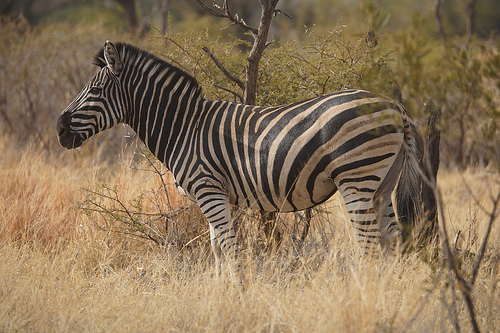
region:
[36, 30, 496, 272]
zebra is black and white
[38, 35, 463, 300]
zebra standing in tall grass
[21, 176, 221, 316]
grass ranging from light brown to blonde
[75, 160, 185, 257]
branches reaching out toward zebra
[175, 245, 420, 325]
bottom of legs hidden by grass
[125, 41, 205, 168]
stripes extending into mane like spears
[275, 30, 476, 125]
greener growth in back of zebra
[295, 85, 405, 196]
tannish-green lines between black stripes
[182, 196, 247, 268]
black lines across front leg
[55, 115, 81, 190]
blade of light grass hanging out of mouth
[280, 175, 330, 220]
stripes getting thinner under belly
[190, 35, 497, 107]
small tree on the side of the zebra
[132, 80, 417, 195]
the zebra is black and white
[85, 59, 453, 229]
the zebra is made of stripes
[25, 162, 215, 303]
tall brownish grass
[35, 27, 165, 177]
zebra has a black nose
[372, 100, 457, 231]
the zebra's tail has long hair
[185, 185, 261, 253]
stripes are smaller on the zebra's legs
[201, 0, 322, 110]
no leaves on the tree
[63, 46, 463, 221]
can only see the left side of the zebra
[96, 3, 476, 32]
looks like it is day time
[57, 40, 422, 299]
zebra has stripes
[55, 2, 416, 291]
zebra standing in front of small tree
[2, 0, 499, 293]
bushes behind zebra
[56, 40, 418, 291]
zebra has a black nose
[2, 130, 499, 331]
grass is tall and brown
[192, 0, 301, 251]
tree is small and bare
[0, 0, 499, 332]
zebra is standing in the savannah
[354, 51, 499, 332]
twigs in front of zebra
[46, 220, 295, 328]
grass is brown and yellow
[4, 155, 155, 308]
grass is brown and yellow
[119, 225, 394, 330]
grass is brown and yellow